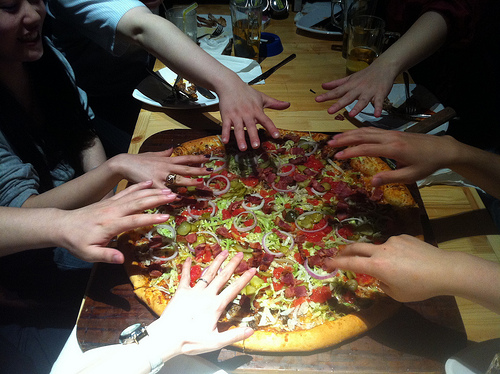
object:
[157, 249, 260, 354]
hands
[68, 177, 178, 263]
hands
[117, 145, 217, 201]
hands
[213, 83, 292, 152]
hands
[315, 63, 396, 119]
hands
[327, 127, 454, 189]
hands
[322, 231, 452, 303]
hands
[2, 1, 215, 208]
girl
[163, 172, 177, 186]
ring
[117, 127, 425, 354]
pizza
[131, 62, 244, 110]
plates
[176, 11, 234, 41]
plates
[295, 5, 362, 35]
plates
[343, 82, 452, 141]
plates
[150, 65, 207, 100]
silverware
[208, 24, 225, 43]
silverware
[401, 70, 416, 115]
silverware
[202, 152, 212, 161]
fingernails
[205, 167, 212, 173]
fingernails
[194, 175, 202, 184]
fingernails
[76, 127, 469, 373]
tray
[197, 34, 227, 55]
napkin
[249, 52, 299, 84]
knife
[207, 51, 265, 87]
napkin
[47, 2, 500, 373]
table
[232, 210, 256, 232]
onion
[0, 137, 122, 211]
arm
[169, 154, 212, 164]
finger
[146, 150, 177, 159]
thumb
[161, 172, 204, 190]
finger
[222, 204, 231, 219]
tomato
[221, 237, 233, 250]
lettuce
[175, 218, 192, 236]
pickel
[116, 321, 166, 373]
watch